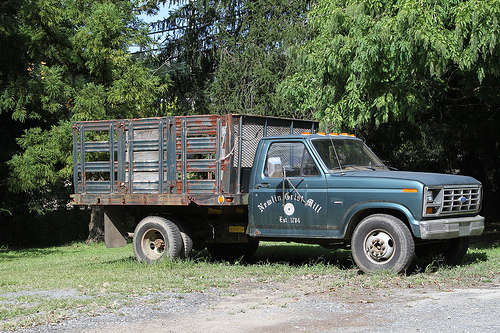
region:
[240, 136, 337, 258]
the truck belongs to Newlin Grist Mill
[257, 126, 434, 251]
the truck is blue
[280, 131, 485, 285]
the truck is an old Ford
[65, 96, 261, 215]
the bed of the truck has steel rails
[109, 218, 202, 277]
the tires appear to be nearly bald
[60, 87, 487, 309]
the truck is rather old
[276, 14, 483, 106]
the trees are very green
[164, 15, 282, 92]
an evergreen tree stands in the background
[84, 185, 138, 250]
the truck has mud flaps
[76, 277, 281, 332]
gravel is in the foreground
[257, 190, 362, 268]
The truck has white letters on its door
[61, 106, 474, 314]
The truck is parked in the grass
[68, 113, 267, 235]
The back of the truck is holding an object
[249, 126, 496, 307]
No one is in the truck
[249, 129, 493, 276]
The truck is green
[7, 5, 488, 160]
The trees are covered the electrical lines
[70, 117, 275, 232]
The back of the truck is rusty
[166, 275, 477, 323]
Dirt is covering the ground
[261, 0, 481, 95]
The sun is shining on the trees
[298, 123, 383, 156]
The lights on top of the truck are orange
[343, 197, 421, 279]
old black tire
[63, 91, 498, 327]
old truck with rusty trailer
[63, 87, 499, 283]
old green pickup truck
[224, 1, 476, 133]
trees with green leaves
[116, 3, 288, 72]
telephone wire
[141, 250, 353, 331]
grass and patches of gravel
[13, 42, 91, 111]
flowers on a tree branch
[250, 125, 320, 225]
left side view mirror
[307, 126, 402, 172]
windshield of a truck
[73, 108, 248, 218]
rusty metal grid trailer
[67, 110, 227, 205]
A rusty trailer railing.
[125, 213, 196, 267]
A set of two tires in the rear of the chassis.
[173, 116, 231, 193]
Flecks of rust adorn the railing.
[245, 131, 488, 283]
A green truck with a large rear view mirror.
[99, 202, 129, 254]
A faded black mudflap.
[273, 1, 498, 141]
A tree with dense foliage overlooking the truck.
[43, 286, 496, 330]
A dirt road amid the trees.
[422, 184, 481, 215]
A faded truck grille with a small logo in the center.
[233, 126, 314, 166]
Wire frame along the front of the trailer.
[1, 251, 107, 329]
Patches of grass along the dirt road.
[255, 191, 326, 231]
white lettering on the side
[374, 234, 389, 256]
metal bolts on the wheel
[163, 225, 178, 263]
thick black rubber on the tire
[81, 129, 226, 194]
a rusty green cage on the truck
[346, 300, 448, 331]
a paved area near the truck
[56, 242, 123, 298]
green grass growing around the truck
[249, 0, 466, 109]
tall trees hanging over the vehical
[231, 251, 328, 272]
black shadow under the truck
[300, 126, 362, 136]
yellow caution light on top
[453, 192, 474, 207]
blue and silver company logo